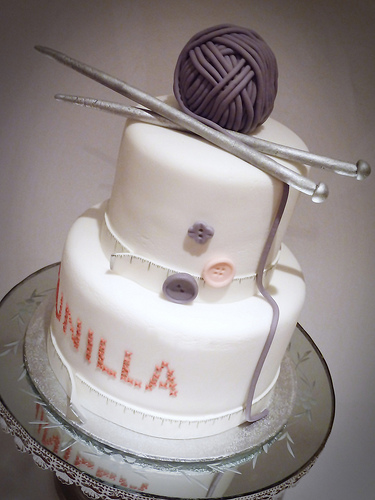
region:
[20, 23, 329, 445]
Cake with craft theme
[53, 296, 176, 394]
Letters in cross stitched icing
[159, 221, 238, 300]
Three buttons on side of cake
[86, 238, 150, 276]
Tape measure made of fondant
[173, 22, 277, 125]
Ball of yarn made of fondant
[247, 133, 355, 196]
Two knitting needles on top of cake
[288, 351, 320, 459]
Glass cake stand with etched design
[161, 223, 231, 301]
Pink and gray buttons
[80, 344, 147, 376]
Pink icing on white cake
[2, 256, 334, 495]
glass table with etchings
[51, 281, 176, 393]
words on cake frosting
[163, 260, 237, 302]
two candy buttons on cake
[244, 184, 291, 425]
yarn on side of cake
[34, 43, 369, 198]
two silver knitting needles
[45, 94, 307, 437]
cake with two tiers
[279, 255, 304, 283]
shadow on top of frosting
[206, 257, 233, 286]
button with four holes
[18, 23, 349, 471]
white cake on sitting on silver platter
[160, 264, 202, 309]
blue fondant button decoration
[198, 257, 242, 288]
pink fondant button design on cake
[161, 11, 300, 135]
ball of purple yarn decoration on cake top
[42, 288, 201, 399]
red writing decoration on side of cake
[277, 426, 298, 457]
leave design on top of glass table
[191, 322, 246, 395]
white fondant on side of cake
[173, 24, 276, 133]
ball of yarn on top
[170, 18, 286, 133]
fake ball of yarn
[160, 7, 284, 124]
purple fake ball of yarn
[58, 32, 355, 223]
crocheting needles on top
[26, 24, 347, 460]
two tier cake on platter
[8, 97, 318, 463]
white cake on platter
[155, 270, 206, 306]
purple button on side of cake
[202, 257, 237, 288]
white button on side of cake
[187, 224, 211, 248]
purple small button on cake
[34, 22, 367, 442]
cake with white frosting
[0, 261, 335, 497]
silver tray on glass table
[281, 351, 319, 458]
design in glass table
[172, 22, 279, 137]
cake decoration shaped like yarn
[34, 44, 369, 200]
two knitting needle decorations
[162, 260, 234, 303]
buttons on white frosting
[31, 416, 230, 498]
reflection of cake on table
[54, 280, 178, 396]
letters on side of cake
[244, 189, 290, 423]
yarn on side of cake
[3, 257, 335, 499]
A plate used for serving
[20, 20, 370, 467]
A themed cake for an occasion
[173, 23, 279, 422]
A fake ball of yarn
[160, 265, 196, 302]
button on the white sculpure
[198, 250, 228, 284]
button on the white sculpure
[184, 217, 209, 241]
button on the white sculpure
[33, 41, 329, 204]
knitting needle on the white sculpure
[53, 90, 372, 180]
knitting needle on the white sculpure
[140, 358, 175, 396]
orange letter on the white sculpure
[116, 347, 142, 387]
orange letter on the white sculpure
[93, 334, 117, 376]
orange letter on the white sculpure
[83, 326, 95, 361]
orange letter on the white sculpure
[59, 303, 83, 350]
orange letter on the white sculpure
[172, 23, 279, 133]
ball next to nails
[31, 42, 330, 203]
nail next to ball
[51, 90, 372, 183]
nail next to ball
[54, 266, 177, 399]
word on side of cake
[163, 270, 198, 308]
button on side of cake